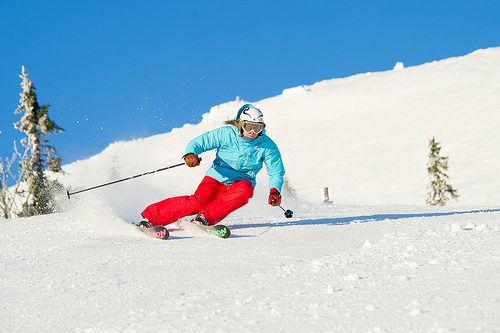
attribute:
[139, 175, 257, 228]
pants — read, red, bright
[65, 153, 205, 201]
pole — black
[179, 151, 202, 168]
hand — brown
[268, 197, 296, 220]
pole — black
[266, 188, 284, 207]
hand — red, black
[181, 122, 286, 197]
jacket — blue, light, puffy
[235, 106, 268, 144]
helmet — white, black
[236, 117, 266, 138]
goggles — white, half face, yellow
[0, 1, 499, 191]
sky — clear, sunny, cloudless, blue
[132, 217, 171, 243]
ski — black, pink, neon pink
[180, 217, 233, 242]
ski — black, green, neon green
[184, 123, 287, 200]
coat — blue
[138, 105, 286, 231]
woman — skiing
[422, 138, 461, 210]
tree — pine, small, scraggly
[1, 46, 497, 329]
snow — snow covered, downhill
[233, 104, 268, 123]
patterns — black swirled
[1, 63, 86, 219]
pine tree — snow covered